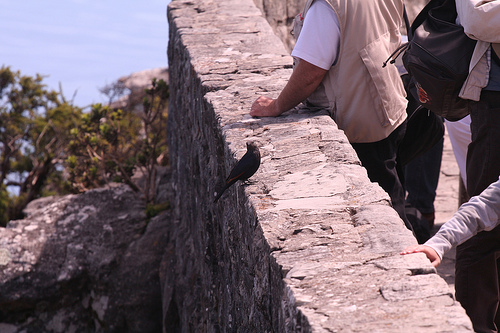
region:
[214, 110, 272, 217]
a bird on a rock wall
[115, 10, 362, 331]
a rock wall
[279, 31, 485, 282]
four people next to a rock wall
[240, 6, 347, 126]
a person leaning against a rock wall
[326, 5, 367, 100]
a person wearing a tan vest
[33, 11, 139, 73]
a body of water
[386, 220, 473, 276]
a person touching a rock wall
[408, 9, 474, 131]
a person carrying a black back pack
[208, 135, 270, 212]
a bird standing on a rock wall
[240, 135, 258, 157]
a bird with its head turned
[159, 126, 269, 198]
a bird on the wall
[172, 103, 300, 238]
a small bird on the wall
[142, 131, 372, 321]
a bird on a rock wall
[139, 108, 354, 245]
a small bird on a rock wall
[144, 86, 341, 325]
a wall made of rock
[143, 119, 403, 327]
a rock wall with a bird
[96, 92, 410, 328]
a rock wall with a small bird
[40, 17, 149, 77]
a blue sky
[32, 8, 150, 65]
a blue sky with clouds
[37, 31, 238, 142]
a sky with clouds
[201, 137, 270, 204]
a bird perched on a wall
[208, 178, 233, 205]
the tail of a bird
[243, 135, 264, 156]
the head of a bird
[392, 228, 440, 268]
a person's hand on a wall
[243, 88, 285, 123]
a hand of a person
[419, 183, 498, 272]
the arm of a person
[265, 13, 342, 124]
the arm of a person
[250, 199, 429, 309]
the rocks of a wall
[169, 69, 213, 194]
the rocks of a wall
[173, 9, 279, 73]
the rocks of a wall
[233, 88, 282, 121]
hand of the person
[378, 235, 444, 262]
hand of the person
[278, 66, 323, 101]
arm of the person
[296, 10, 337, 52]
the shirt is white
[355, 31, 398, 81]
the vest is tan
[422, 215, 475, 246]
the shirt is grey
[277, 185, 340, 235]
the wall is brick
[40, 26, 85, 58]
the water is calm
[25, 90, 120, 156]
trees near the wall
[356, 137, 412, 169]
the pants are black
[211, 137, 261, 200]
a small black bird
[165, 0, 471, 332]
a tall grey brick wall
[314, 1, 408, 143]
a light brown vest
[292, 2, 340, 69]
a man's white t-shirt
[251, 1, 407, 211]
a man standing by wall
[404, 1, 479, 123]
a large black backpack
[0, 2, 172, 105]
a large body of water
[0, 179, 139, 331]
a large grey boulder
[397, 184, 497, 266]
a child's arm on wall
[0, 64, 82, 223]
large green tree in distance